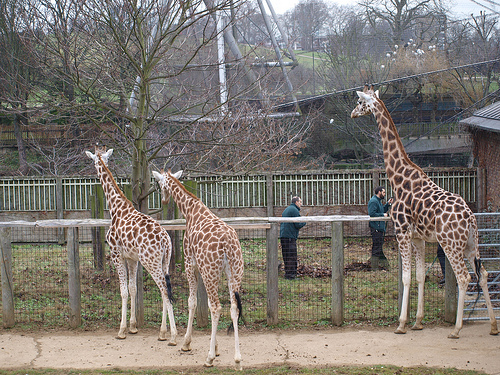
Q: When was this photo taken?
A: During the day.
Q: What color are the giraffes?
A: Brown and white.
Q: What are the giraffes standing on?
A: The ground.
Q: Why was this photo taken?
A: To show the animals.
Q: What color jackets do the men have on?
A: Blue.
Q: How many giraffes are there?
A: Three.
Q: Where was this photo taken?
A: Outside in the giraffe exhibit.